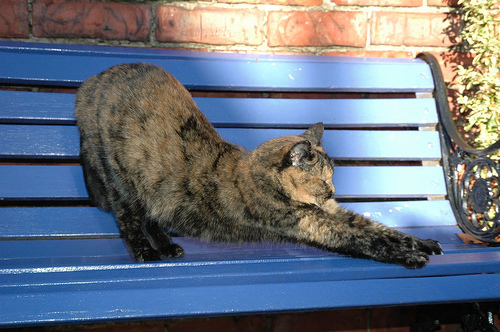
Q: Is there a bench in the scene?
A: Yes, there is a bench.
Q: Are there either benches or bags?
A: Yes, there is a bench.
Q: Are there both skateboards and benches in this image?
A: No, there is a bench but no skateboards.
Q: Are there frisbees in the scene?
A: No, there are no frisbees.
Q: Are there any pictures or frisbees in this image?
A: No, there are no frisbees or pictures.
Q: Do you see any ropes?
A: No, there are no ropes.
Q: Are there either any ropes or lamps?
A: No, there are no ropes or lamps.